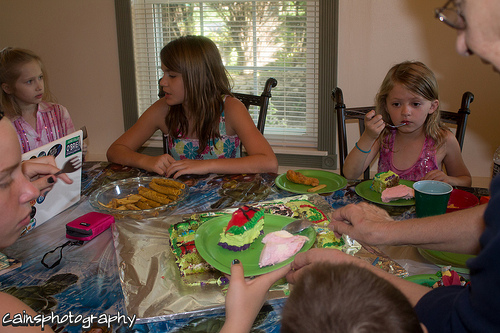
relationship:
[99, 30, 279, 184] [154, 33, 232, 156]
girl has hair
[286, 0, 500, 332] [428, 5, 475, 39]
man wearing glasses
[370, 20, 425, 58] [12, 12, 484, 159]
part of the wall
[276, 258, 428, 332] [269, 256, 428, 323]
head of a head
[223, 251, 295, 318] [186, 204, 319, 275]
hand holding plate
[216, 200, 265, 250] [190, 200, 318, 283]
cake on plate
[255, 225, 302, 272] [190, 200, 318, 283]
ice cream on plate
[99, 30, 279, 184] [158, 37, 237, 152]
girl with hair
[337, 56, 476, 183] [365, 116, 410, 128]
girl with fork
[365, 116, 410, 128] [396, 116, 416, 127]
fork to her mouth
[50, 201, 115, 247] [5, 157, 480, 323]
bag on table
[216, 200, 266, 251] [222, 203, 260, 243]
cake with frosting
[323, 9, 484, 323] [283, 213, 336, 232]
man with spoon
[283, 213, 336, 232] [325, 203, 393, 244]
spoon in his hand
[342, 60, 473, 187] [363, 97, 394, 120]
girl holding fork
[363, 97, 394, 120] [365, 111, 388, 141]
fork in hand